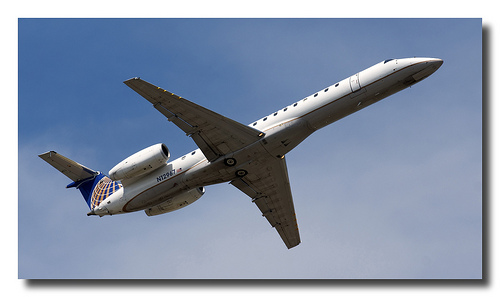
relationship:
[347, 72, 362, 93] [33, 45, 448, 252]
door on plane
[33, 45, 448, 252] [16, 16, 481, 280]
plane in sky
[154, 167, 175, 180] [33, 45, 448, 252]
writing on plane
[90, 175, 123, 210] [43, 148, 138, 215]
logo on tail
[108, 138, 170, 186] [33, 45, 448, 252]
engine on plane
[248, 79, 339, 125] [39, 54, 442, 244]
windows on side of plane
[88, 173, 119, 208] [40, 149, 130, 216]
logo on tail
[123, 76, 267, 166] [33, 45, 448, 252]
wing on side of plane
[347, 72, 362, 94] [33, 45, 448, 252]
door on side of plane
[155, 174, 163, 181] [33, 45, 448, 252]
letter on plane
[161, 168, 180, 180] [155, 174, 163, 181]
numbers on letter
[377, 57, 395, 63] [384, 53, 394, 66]
windshield on cockpit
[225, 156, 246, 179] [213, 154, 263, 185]
wheels on landing gear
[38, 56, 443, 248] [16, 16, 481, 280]
airplane in sky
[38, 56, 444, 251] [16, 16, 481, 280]
plane in sky